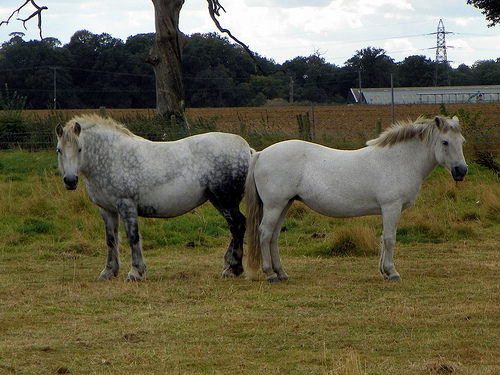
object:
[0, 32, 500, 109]
leaves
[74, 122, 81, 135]
ear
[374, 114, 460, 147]
mane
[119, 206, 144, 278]
leg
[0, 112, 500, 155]
fence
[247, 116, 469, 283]
horse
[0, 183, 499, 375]
field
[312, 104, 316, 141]
post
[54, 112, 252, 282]
horse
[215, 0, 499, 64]
cloudy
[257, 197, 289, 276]
leg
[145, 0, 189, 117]
tree trunk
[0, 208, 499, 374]
grass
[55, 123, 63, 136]
ear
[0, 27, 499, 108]
tree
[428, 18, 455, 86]
pole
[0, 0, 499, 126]
distance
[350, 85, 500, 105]
building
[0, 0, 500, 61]
skies